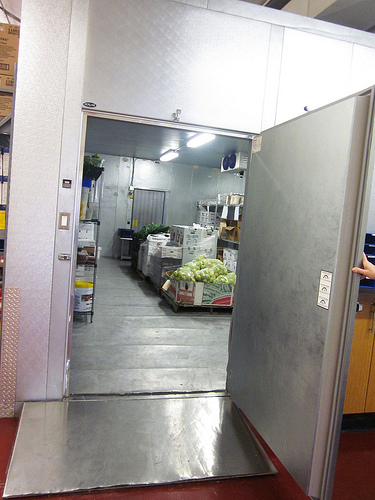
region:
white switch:
[41, 190, 87, 233]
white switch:
[53, 197, 84, 242]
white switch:
[40, 200, 112, 271]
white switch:
[57, 199, 89, 265]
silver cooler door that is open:
[64, 91, 352, 433]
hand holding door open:
[304, 182, 372, 340]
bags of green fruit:
[158, 245, 245, 290]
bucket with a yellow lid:
[61, 267, 112, 315]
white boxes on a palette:
[147, 217, 238, 303]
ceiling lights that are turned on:
[142, 116, 224, 181]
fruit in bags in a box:
[160, 250, 242, 326]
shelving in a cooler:
[191, 181, 246, 261]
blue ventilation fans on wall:
[206, 146, 260, 178]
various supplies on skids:
[137, 211, 244, 315]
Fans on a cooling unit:
[219, 147, 239, 174]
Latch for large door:
[169, 107, 188, 124]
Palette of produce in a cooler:
[172, 257, 235, 313]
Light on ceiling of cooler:
[155, 144, 180, 162]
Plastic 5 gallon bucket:
[67, 276, 99, 317]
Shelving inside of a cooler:
[72, 149, 107, 337]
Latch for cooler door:
[53, 249, 74, 263]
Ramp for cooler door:
[11, 402, 266, 492]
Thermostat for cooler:
[124, 176, 137, 202]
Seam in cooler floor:
[115, 320, 214, 337]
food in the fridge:
[151, 253, 232, 299]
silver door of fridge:
[237, 146, 320, 246]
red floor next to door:
[345, 451, 363, 476]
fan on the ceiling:
[205, 151, 247, 181]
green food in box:
[177, 255, 246, 288]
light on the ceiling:
[152, 142, 182, 169]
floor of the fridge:
[99, 307, 162, 361]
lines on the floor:
[114, 307, 170, 380]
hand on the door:
[348, 240, 371, 272]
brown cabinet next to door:
[354, 330, 373, 367]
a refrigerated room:
[11, 4, 372, 490]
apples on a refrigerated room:
[156, 247, 236, 307]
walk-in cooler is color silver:
[15, 1, 371, 497]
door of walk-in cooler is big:
[60, 66, 363, 494]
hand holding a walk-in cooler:
[187, 185, 371, 372]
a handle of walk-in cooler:
[317, 282, 373, 334]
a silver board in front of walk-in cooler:
[4, 387, 290, 496]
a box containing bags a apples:
[159, 249, 240, 317]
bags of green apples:
[166, 249, 237, 291]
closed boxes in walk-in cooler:
[128, 211, 224, 279]